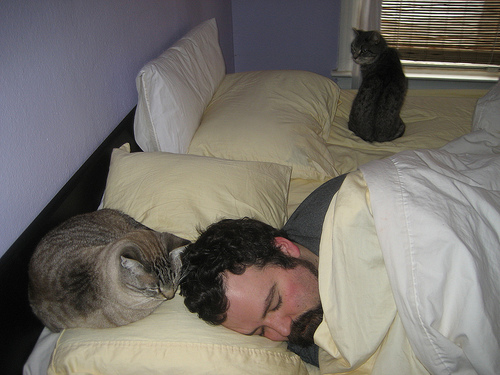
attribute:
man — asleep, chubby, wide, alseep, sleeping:
[214, 177, 462, 341]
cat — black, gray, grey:
[45, 199, 182, 329]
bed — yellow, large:
[168, 60, 499, 312]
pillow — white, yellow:
[199, 65, 325, 177]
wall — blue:
[49, 17, 110, 68]